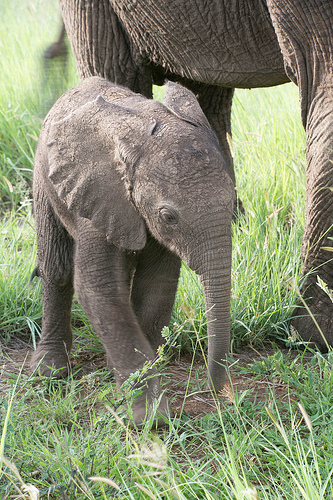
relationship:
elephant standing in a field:
[25, 70, 240, 422] [1, 58, 313, 490]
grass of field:
[1, 0, 332, 499] [1, 58, 313, 490]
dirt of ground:
[0, 335, 331, 465] [0, 1, 331, 499]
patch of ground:
[8, 346, 310, 435] [0, 1, 331, 499]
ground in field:
[0, 1, 331, 499] [0, 3, 330, 497]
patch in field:
[8, 346, 310, 435] [0, 3, 330, 497]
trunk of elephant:
[185, 210, 230, 399] [25, 70, 240, 422]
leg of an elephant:
[286, 68, 331, 351] [42, 0, 332, 350]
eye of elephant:
[154, 203, 178, 228] [25, 70, 240, 422]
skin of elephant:
[199, 20, 257, 61] [25, 70, 240, 422]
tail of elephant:
[36, 20, 77, 98] [42, 0, 332, 350]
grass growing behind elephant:
[252, 97, 299, 198] [25, 70, 240, 422]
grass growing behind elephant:
[252, 97, 299, 198] [72, 0, 332, 94]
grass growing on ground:
[1, 340, 333, 500] [19, 382, 331, 465]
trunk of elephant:
[185, 210, 230, 399] [9, 71, 253, 370]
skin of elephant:
[84, 161, 109, 194] [25, 70, 240, 422]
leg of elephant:
[137, 253, 179, 360] [24, 78, 244, 356]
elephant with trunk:
[25, 70, 240, 422] [185, 210, 230, 399]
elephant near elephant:
[25, 70, 240, 422] [35, 0, 332, 358]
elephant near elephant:
[25, 70, 240, 422] [42, 0, 332, 350]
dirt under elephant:
[0, 335, 331, 465] [13, 68, 248, 330]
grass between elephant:
[4, 95, 329, 474] [25, 70, 240, 422]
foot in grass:
[68, 239, 180, 435] [1, 0, 332, 499]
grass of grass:
[1, 340, 333, 500] [42, 360, 316, 461]